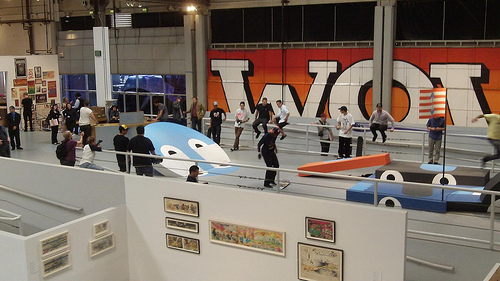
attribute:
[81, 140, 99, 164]
shirt — white, black sleeves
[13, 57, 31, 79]
pictures — several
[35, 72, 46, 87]
pictures — several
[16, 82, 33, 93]
pictures — several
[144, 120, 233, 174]
ramp — round, blue, white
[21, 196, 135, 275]
partition — white wall 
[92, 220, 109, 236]
picture — Four , white , frames 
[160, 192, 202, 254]
pictures — three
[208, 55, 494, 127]
lettering — white 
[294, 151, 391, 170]
orange ramp — orange s, black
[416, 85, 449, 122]
flag — orange, white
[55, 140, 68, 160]
backpack — black 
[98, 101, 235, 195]
ramp — orange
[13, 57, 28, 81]
picture — small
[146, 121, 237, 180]
ramp — blue, white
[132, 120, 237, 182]
object — blue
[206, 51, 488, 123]
wall — orange painted , Red 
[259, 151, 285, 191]
black pants — black 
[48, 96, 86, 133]
shirt — black 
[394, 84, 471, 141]
flag — white striped, Orange 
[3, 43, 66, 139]
wall — white 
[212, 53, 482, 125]
letters — white 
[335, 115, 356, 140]
shirt — white 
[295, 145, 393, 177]
block — orange 